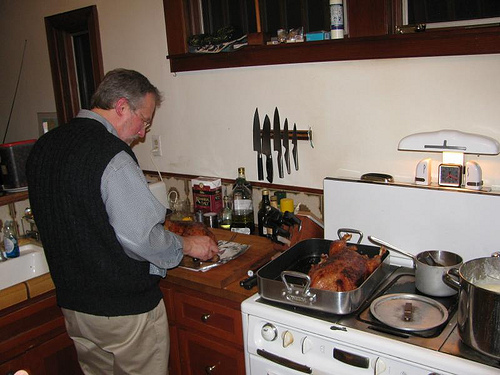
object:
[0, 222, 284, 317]
wooden counter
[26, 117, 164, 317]
black sweater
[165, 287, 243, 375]
cupboard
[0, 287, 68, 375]
cupboard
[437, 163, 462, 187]
clock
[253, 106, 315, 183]
knives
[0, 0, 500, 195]
wall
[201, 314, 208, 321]
knob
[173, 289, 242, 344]
drawer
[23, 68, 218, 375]
guy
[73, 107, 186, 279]
shirt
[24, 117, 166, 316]
sweater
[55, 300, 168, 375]
khaki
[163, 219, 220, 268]
meat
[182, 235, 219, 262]
hand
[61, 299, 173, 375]
pants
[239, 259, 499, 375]
oven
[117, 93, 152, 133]
glasses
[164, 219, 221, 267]
dinner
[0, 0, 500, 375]
kitchen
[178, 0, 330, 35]
windows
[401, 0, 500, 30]
windows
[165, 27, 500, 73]
sills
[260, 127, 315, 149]
rack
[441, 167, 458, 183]
time